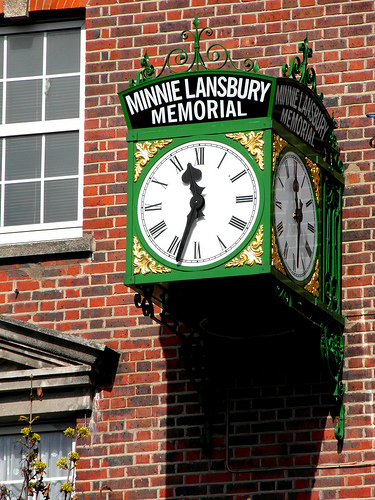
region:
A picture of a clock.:
[91, 6, 359, 381]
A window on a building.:
[6, 23, 84, 241]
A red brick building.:
[13, 262, 352, 483]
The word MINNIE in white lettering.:
[115, 73, 187, 114]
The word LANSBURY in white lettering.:
[181, 75, 272, 100]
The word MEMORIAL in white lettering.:
[150, 95, 248, 128]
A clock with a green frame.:
[119, 43, 369, 350]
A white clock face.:
[136, 137, 265, 265]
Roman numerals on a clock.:
[128, 136, 262, 270]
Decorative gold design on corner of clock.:
[119, 129, 267, 273]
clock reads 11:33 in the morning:
[135, 129, 261, 269]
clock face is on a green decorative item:
[135, 133, 263, 265]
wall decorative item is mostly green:
[110, 77, 358, 435]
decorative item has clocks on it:
[106, 24, 354, 369]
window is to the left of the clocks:
[0, 21, 91, 258]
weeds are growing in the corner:
[1, 368, 114, 499]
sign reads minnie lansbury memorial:
[127, 65, 270, 135]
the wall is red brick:
[1, 106, 374, 492]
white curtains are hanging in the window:
[1, 426, 70, 498]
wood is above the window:
[0, 309, 121, 430]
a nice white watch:
[137, 138, 260, 265]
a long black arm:
[172, 204, 205, 261]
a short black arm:
[179, 159, 202, 196]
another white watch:
[274, 142, 324, 286]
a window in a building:
[0, 20, 81, 239]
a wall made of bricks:
[1, 2, 373, 498]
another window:
[2, 425, 75, 494]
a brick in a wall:
[101, 455, 134, 466]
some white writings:
[120, 72, 271, 120]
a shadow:
[164, 347, 317, 498]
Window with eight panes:
[11, 2, 103, 258]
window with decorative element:
[2, 307, 117, 491]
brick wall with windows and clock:
[1, 9, 368, 492]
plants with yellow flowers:
[11, 404, 80, 490]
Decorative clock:
[101, 16, 357, 397]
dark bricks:
[100, 402, 186, 495]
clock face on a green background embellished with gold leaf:
[119, 126, 275, 286]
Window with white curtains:
[5, 402, 120, 490]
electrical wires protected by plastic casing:
[210, 378, 361, 482]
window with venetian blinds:
[7, 17, 94, 266]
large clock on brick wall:
[56, 66, 354, 336]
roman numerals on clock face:
[135, 135, 257, 274]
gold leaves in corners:
[128, 135, 263, 278]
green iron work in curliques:
[114, 15, 284, 79]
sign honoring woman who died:
[108, 65, 284, 128]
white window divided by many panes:
[5, 24, 88, 235]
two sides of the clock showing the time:
[127, 123, 324, 291]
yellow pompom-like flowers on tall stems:
[4, 423, 118, 491]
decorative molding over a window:
[6, 305, 120, 433]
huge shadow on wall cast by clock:
[141, 268, 336, 483]